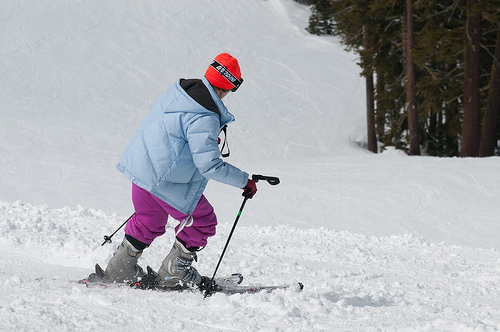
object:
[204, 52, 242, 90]
hat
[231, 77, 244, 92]
goggles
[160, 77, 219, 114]
hood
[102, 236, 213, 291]
boots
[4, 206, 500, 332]
hill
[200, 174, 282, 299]
ski pole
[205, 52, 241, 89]
beanie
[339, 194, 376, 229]
snow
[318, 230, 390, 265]
ground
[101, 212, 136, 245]
hooker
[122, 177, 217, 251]
trouser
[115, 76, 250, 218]
jacket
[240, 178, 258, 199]
glove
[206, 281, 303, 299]
skate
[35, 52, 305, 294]
person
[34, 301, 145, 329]
tracks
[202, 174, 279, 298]
pole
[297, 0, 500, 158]
trees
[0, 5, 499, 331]
snow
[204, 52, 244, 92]
head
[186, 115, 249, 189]
arm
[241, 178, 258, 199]
hand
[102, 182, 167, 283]
leg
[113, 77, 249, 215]
coat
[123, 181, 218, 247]
pants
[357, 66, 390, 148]
trunk